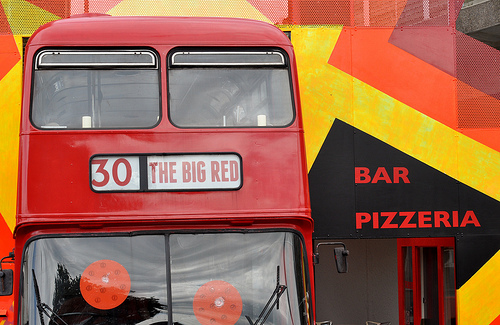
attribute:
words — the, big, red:
[147, 154, 258, 199]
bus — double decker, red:
[11, 3, 339, 321]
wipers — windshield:
[26, 255, 291, 323]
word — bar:
[347, 156, 427, 193]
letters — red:
[349, 154, 423, 192]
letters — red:
[355, 199, 484, 231]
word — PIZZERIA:
[347, 197, 479, 247]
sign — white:
[89, 149, 247, 193]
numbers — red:
[87, 145, 136, 205]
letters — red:
[144, 152, 255, 192]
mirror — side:
[309, 234, 354, 287]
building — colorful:
[275, 4, 484, 314]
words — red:
[343, 152, 483, 251]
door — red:
[387, 219, 467, 322]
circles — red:
[74, 256, 240, 323]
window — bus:
[11, 218, 336, 322]